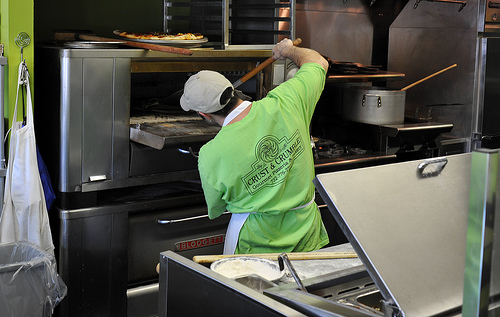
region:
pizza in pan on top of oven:
[114, 28, 213, 47]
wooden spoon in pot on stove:
[396, 57, 458, 95]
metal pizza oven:
[61, 39, 311, 195]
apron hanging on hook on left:
[0, 55, 55, 273]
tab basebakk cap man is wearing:
[173, 66, 238, 118]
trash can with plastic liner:
[0, 241, 62, 315]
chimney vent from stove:
[356, 7, 413, 85]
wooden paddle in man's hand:
[233, 33, 298, 90]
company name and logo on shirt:
[239, 125, 299, 193]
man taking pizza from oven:
[181, 32, 336, 262]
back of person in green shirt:
[198, 37, 327, 258]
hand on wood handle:
[230, 36, 325, 117]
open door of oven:
[64, 49, 294, 188]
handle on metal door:
[318, 152, 473, 314]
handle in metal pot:
[348, 62, 458, 126]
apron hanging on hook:
[0, 60, 52, 247]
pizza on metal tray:
[112, 29, 209, 51]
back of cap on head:
[179, 69, 236, 130]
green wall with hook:
[8, 0, 35, 115]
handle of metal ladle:
[276, 252, 311, 294]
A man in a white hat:
[168, 62, 242, 122]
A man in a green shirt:
[181, 85, 342, 247]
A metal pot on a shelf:
[339, 77, 416, 130]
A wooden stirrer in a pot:
[394, 51, 468, 106]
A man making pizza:
[142, 35, 331, 135]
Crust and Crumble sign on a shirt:
[235, 123, 319, 206]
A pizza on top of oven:
[106, 11, 224, 62]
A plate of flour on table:
[202, 246, 303, 296]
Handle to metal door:
[410, 153, 456, 182]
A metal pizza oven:
[59, 34, 301, 193]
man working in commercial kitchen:
[15, 8, 488, 305]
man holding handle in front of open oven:
[125, 31, 325, 157]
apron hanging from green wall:
[2, 22, 62, 242]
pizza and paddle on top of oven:
[60, 21, 285, 51]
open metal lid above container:
[167, 150, 467, 306]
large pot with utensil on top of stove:
[350, 40, 451, 146]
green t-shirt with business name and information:
[191, 61, 331, 256]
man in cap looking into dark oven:
[175, 70, 246, 125]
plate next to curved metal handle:
[210, 242, 305, 293]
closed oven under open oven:
[63, 111, 234, 292]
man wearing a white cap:
[179, 65, 232, 112]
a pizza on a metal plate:
[113, 24, 207, 44]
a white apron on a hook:
[0, 57, 56, 256]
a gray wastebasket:
[2, 242, 69, 315]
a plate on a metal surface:
[211, 253, 285, 284]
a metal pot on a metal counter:
[338, 79, 405, 126]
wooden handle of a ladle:
[398, 63, 457, 91]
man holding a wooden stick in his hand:
[233, 34, 300, 111]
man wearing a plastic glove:
[272, 38, 293, 57]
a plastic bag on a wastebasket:
[0, 240, 67, 310]